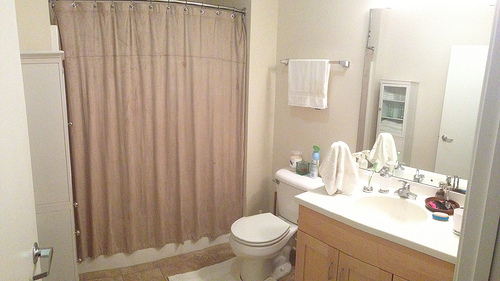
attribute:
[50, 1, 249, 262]
shower curtain — stretched across, beige, pulled, brownish tan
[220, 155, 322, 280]
toilet — closed, porcelain, white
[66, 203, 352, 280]
floor — tan, tiled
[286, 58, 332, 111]
towel — white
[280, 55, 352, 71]
rack — for towels, metal, silver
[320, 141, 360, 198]
towel — draped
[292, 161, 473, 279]
sink — white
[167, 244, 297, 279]
mat — white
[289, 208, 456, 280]
cabinet — white, wooden, double doors, brown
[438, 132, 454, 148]
knob — silver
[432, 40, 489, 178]
door — bathroom door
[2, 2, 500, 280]
bathroom — mid sized, tan, white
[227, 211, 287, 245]
seat — down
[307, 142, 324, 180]
can — air freshener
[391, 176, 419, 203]
faucet — stainless steel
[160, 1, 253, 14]
bar — metal